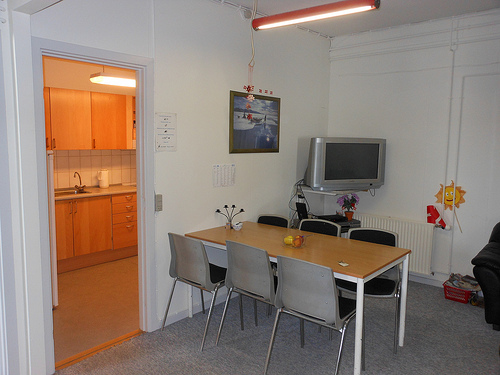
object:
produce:
[282, 234, 293, 246]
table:
[183, 221, 413, 374]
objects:
[456, 279, 480, 292]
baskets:
[441, 273, 479, 304]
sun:
[433, 180, 466, 213]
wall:
[326, 8, 499, 298]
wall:
[10, 0, 332, 374]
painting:
[226, 90, 280, 154]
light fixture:
[251, 4, 379, 32]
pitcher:
[94, 168, 110, 190]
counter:
[53, 184, 138, 274]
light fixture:
[87, 72, 137, 88]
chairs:
[260, 255, 364, 374]